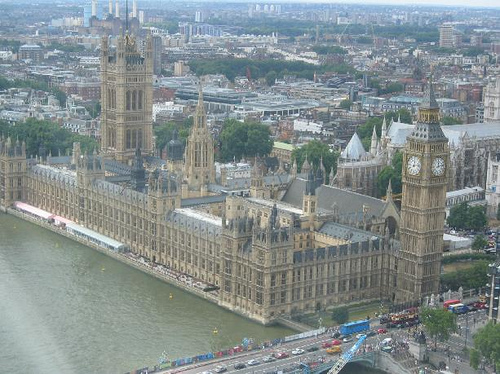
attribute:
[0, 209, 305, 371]
water — body , calm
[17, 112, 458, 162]
trees — grove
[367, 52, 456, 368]
tower — tall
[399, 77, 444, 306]
clock tower — large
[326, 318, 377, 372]
crane — blue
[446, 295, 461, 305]
bus — double decker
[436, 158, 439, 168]
hand — minute hand